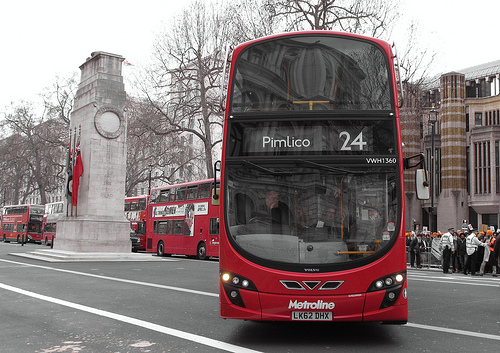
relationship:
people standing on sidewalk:
[408, 226, 498, 269] [414, 256, 492, 278]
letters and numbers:
[253, 131, 315, 154] [338, 131, 368, 156]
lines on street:
[3, 256, 218, 347] [3, 239, 499, 353]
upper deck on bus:
[151, 183, 220, 205] [146, 178, 221, 265]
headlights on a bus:
[222, 268, 408, 292] [220, 35, 414, 321]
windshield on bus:
[232, 47, 398, 266] [220, 35, 414, 321]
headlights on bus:
[222, 268, 408, 292] [220, 35, 414, 321]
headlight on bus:
[370, 275, 408, 287] [220, 35, 414, 321]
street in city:
[3, 239, 499, 353] [1, 2, 496, 351]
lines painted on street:
[3, 256, 218, 347] [3, 239, 499, 353]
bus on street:
[220, 35, 414, 321] [3, 239, 499, 353]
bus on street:
[146, 178, 221, 265] [3, 239, 499, 353]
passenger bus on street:
[41, 201, 66, 247] [3, 239, 499, 353]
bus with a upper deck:
[146, 178, 221, 265] [151, 183, 220, 205]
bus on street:
[6, 202, 42, 244] [3, 239, 499, 353]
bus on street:
[126, 194, 149, 247] [3, 239, 499, 353]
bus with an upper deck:
[146, 178, 221, 265] [151, 183, 220, 205]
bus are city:
[0, 202, 42, 244] [1, 2, 496, 351]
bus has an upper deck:
[146, 178, 221, 265] [151, 183, 220, 205]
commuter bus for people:
[220, 35, 414, 321] [408, 226, 498, 269]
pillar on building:
[438, 74, 473, 245] [405, 65, 500, 259]